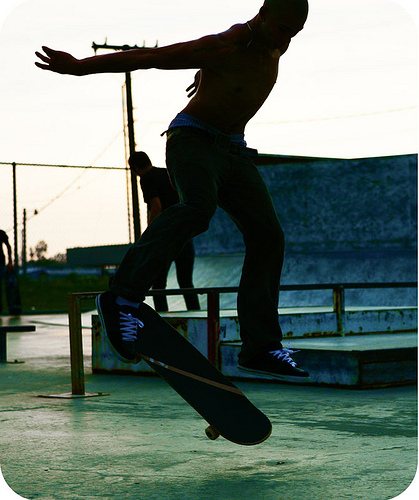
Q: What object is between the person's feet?
A: Skateboard.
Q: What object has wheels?
A: Skateboard.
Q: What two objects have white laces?
A: Tennis shoes.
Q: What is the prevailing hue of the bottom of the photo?
A: Green.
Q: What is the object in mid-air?
A: Skateboard.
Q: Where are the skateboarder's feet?
A: In mid air.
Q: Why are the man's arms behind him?
A: He is doing a trick.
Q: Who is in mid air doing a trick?
A: A skateboarder.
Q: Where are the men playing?
A: In a skateboard park.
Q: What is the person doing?
A: A skateboard trick.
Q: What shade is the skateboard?
A: Black.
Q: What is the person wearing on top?
A: No shirt.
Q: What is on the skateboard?
A: A diagonal.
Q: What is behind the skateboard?
A: A railing.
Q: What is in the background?
A: A building.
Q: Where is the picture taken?
A: Skatepark.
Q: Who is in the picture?
A: A boy.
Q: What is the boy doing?
A: Skateboarding.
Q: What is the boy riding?
A: A skateboard.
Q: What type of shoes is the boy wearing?
A: Chucks.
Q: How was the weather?
A: Calm.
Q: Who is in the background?
A: A skateboarder.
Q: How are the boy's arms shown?
A: Extended behind him.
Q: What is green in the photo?
A: Ground.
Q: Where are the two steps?
A: On the ramp.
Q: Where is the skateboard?
A: In the air.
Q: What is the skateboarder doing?
A: A trick.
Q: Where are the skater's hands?
A: Behind his back.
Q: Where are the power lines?
A: Behind the skaters.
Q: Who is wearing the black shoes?
A: The skateboarder.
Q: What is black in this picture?
A: The shoes.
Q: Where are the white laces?
A: On the shoes.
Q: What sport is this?
A: Skateboarding.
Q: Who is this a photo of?
A: People.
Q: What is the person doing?
A: Skateboarding.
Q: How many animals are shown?
A: None.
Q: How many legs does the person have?
A: Two.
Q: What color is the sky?
A: White.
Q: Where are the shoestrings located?
A: In the shoes.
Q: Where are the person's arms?
A: Behind them.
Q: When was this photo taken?
A: Daytime.